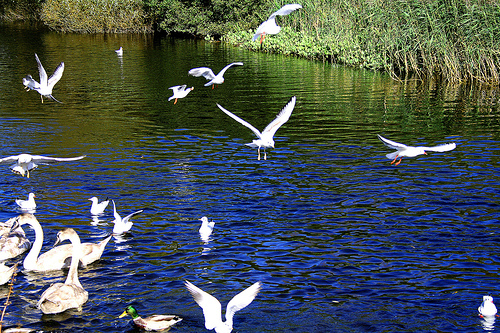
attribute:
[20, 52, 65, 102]
bird — white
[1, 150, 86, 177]
bird — white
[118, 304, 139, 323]
face — green 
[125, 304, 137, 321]
face — green 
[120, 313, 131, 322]
bill — yellow 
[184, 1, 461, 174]
birds — white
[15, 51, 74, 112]
bird — white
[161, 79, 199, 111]
bird — white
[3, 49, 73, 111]
bird — white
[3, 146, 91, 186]
bird — white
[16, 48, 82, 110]
bird — white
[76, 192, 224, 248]
birds — white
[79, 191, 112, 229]
bird — white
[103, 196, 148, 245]
bird — white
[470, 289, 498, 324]
bird — white